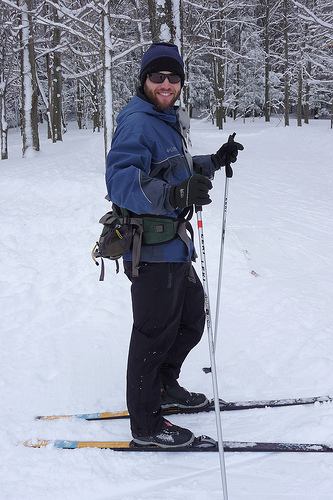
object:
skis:
[194, 130, 236, 500]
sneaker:
[130, 418, 193, 451]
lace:
[164, 421, 173, 427]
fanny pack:
[143, 216, 175, 244]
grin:
[157, 91, 173, 97]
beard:
[143, 81, 181, 112]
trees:
[0, 0, 332, 160]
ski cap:
[139, 42, 184, 87]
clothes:
[105, 86, 217, 436]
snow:
[0, 0, 333, 500]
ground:
[0, 115, 333, 500]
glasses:
[146, 72, 182, 83]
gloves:
[169, 141, 244, 210]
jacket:
[105, 93, 216, 263]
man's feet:
[130, 383, 210, 450]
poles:
[192, 132, 235, 499]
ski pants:
[123, 261, 205, 439]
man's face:
[146, 69, 182, 106]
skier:
[93, 41, 243, 455]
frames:
[146, 71, 181, 78]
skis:
[24, 395, 332, 451]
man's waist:
[112, 195, 184, 259]